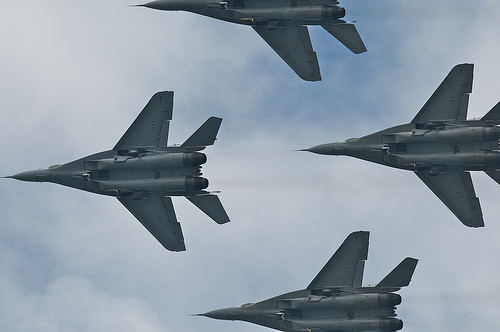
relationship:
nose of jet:
[1, 169, 47, 191] [3, 85, 240, 268]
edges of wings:
[94, 116, 138, 155] [79, 87, 201, 257]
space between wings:
[171, 102, 199, 142] [79, 87, 201, 257]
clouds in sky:
[8, 6, 249, 96] [2, 2, 499, 331]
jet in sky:
[3, 85, 240, 268] [2, 2, 499, 331]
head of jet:
[1, 169, 47, 191] [3, 85, 240, 268]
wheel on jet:
[427, 167, 442, 176] [280, 50, 499, 245]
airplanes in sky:
[13, 5, 492, 324] [2, 2, 499, 331]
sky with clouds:
[2, 2, 499, 331] [8, 6, 249, 96]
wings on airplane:
[79, 87, 201, 257] [3, 85, 240, 268]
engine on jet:
[143, 149, 212, 170] [3, 85, 240, 268]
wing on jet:
[110, 192, 191, 256] [3, 85, 240, 268]